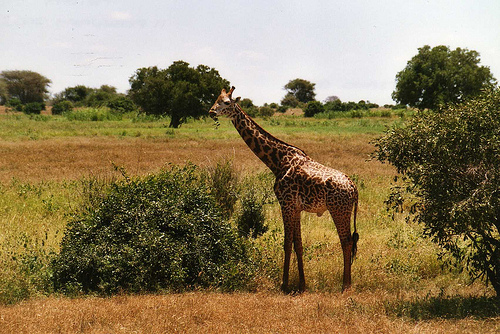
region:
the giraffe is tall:
[201, 81, 401, 303]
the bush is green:
[89, 155, 274, 324]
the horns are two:
[210, 80, 255, 108]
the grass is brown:
[154, 289, 271, 332]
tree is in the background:
[128, 55, 240, 132]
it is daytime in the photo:
[6, 9, 487, 326]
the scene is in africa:
[9, 13, 489, 330]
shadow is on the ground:
[383, 293, 475, 328]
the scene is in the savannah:
[8, 7, 498, 325]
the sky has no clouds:
[66, 10, 478, 46]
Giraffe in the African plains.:
[203, 73, 383, 330]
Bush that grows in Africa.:
[40, 148, 279, 318]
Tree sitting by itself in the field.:
[92, 41, 234, 137]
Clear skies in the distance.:
[27, 10, 498, 53]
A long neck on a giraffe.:
[207, 89, 315, 179]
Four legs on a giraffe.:
[269, 190, 366, 297]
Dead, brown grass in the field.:
[25, 286, 365, 332]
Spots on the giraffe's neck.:
[249, 132, 284, 169]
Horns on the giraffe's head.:
[211, 80, 244, 95]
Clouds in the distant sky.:
[97, 7, 229, 65]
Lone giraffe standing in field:
[11, 22, 488, 312]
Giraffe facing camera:
[199, 80, 242, 120]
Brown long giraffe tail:
[343, 179, 363, 253]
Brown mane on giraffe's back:
[237, 120, 314, 147]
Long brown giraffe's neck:
[203, 77, 300, 172]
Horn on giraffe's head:
[219, 80, 241, 98]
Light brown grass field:
[23, 287, 429, 332]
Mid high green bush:
[57, 157, 269, 292]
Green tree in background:
[126, 56, 228, 132]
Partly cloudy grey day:
[76, 9, 497, 54]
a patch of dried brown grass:
[2, 138, 413, 183]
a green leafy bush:
[52, 159, 252, 295]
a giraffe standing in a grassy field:
[209, 79, 362, 297]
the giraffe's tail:
[349, 189, 359, 253]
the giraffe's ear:
[232, 97, 242, 105]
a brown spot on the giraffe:
[259, 143, 271, 155]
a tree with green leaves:
[132, 58, 227, 128]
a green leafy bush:
[379, 81, 499, 300]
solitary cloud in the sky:
[105, 6, 129, 23]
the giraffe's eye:
[222, 99, 229, 107]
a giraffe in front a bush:
[26, 79, 391, 303]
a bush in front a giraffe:
[31, 83, 378, 297]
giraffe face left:
[206, 88, 384, 303]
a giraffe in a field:
[13, 51, 487, 331]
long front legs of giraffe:
[268, 209, 313, 296]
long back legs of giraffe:
[336, 211, 360, 293]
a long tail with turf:
[351, 185, 365, 263]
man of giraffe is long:
[236, 100, 304, 159]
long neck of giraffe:
[231, 112, 289, 168]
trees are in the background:
[0, 40, 495, 124]